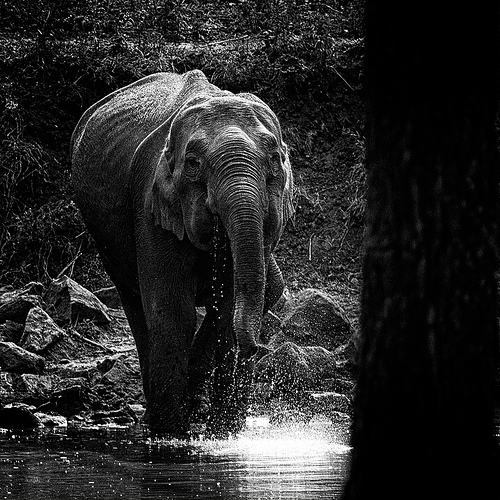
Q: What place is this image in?
A: It is at the forest.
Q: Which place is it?
A: It is a forest.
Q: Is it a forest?
A: Yes, it is a forest.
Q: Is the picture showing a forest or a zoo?
A: It is showing a forest.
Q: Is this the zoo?
A: No, it is the forest.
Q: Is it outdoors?
A: Yes, it is outdoors.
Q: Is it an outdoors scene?
A: Yes, it is outdoors.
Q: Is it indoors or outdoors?
A: It is outdoors.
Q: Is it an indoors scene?
A: No, it is outdoors.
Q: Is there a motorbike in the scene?
A: No, there are no motorcycles.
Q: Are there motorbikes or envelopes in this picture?
A: No, there are no motorbikes or envelopes.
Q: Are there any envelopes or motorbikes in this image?
A: No, there are no motorbikes or envelopes.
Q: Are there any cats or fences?
A: No, there are no fences or cats.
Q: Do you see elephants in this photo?
A: Yes, there is an elephant.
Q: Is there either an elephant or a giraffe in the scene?
A: Yes, there is an elephant.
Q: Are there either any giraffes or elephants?
A: Yes, there is an elephant.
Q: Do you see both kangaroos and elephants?
A: No, there is an elephant but no kangaroos.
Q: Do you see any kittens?
A: No, there are no kittens.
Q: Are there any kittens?
A: No, there are no kittens.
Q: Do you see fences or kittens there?
A: No, there are no kittens or fences.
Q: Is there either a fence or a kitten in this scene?
A: No, there are no kittens or fences.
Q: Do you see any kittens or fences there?
A: No, there are no kittens or fences.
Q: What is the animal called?
A: The animal is an elephant.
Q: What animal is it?
A: The animal is an elephant.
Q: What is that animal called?
A: This is an elephant.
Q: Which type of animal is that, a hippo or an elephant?
A: This is an elephant.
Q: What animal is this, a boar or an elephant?
A: This is an elephant.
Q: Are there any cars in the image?
A: No, there are no cars.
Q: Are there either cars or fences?
A: No, there are no cars or fences.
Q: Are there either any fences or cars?
A: No, there are no cars or fences.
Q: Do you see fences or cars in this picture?
A: No, there are no cars or fences.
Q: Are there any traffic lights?
A: No, there are no traffic lights.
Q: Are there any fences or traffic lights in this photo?
A: No, there are no traffic lights or fences.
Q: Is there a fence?
A: No, there are no fences.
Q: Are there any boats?
A: No, there are no boats.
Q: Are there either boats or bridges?
A: No, there are no boats or bridges.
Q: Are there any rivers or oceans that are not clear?
A: No, there is a river but it is clear.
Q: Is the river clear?
A: Yes, the river is clear.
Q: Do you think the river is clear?
A: Yes, the river is clear.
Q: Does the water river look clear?
A: Yes, the river is clear.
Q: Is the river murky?
A: No, the river is clear.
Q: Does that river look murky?
A: No, the river is clear.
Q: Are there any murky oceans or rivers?
A: No, there is a river but it is clear.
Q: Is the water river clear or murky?
A: The river is clear.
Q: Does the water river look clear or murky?
A: The river is clear.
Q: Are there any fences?
A: No, there are no fences.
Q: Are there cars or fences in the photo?
A: No, there are no fences or cars.